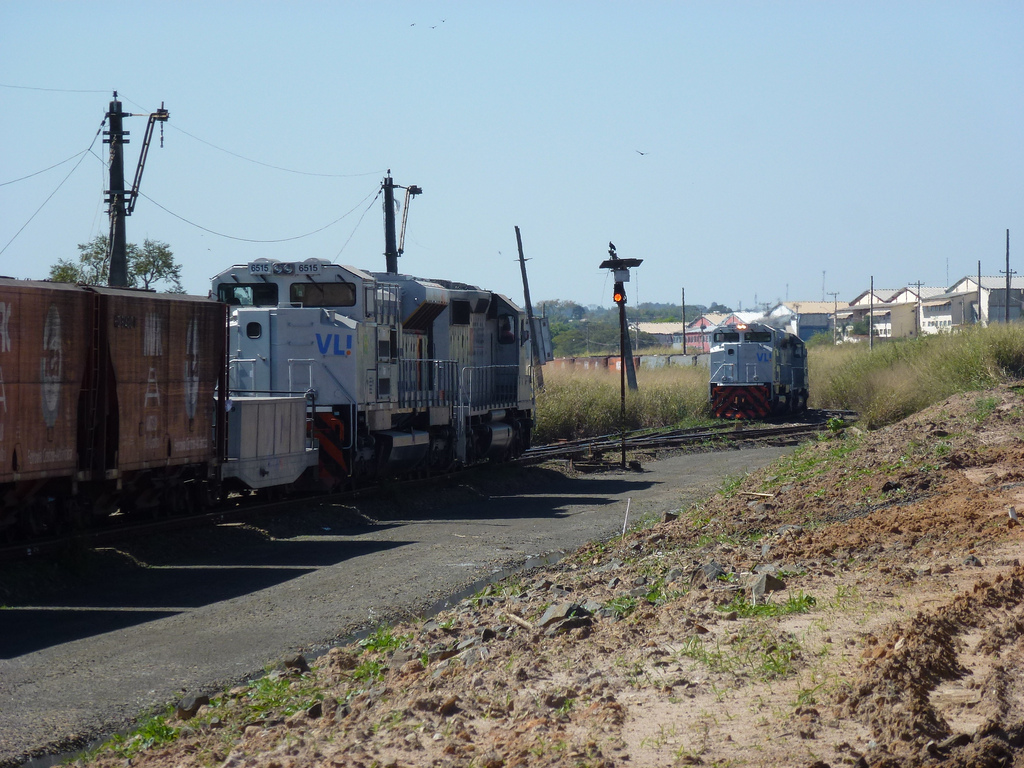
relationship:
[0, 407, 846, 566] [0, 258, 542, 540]
track under train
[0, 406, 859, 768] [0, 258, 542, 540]
track under train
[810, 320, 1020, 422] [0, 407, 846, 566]
grass under track